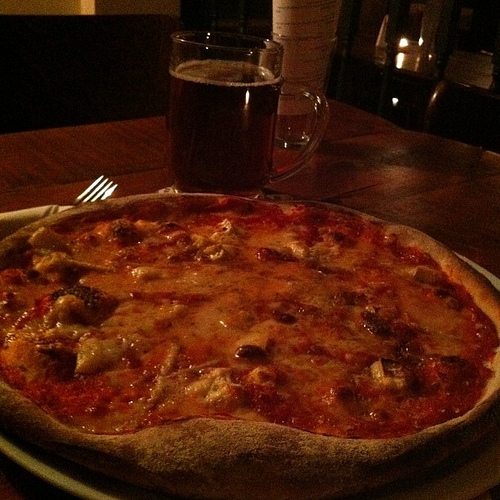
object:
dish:
[1, 188, 498, 499]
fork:
[0, 172, 119, 254]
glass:
[163, 28, 328, 204]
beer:
[165, 56, 281, 196]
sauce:
[323, 328, 471, 409]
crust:
[0, 188, 499, 494]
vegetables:
[30, 220, 375, 405]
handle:
[263, 79, 331, 184]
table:
[319, 62, 498, 171]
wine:
[158, 64, 280, 197]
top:
[76, 172, 119, 209]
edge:
[405, 234, 500, 309]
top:
[4, 102, 496, 297]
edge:
[0, 97, 268, 150]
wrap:
[0, 197, 81, 228]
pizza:
[1, 179, 498, 499]